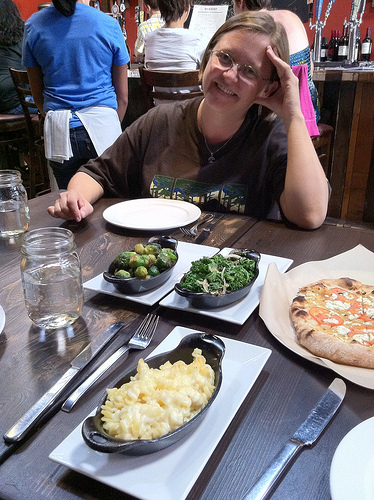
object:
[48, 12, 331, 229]
lady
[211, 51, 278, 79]
glasses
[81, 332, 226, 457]
pan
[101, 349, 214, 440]
mac and cheese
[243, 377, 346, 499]
knife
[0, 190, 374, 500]
table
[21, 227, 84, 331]
glass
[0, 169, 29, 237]
glass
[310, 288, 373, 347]
tomato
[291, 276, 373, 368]
pizza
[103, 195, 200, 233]
plate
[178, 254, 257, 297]
vegetable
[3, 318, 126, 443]
knife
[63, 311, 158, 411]
fork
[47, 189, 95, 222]
hand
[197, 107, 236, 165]
necklace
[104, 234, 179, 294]
bowl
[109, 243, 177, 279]
brussel sprouts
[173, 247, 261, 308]
bowl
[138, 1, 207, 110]
lady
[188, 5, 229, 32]
menu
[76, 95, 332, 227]
shirt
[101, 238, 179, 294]
dish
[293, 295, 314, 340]
burnt part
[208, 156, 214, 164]
pendant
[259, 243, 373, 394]
paper towel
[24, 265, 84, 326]
water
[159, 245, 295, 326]
tray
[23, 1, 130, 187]
waiter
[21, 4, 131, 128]
shirt